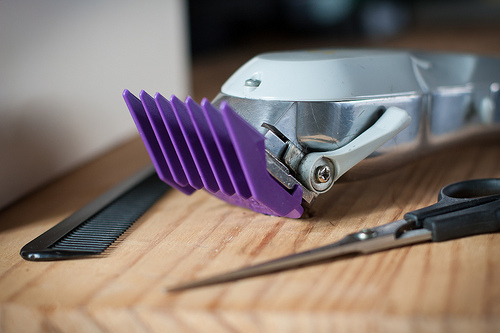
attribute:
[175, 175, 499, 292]
scissors — gray, black, metal, partial, for hair cutting, small, shiny, tipped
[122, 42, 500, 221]
razor machine — white, gray, purple, partial, for hair cutting, electric, silver, for cutting hair, upside down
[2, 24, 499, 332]
table — partial, edged, wooden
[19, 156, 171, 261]
comb — black, fine tooth, top section, long, plastic, fine toothed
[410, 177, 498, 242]
handle — black, plastic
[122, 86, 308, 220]
blade — purple, large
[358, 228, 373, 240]
screw — little, silver, metal, round, shiny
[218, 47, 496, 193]
section — gray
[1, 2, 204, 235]
wall — small part, white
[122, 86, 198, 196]
part — tiny